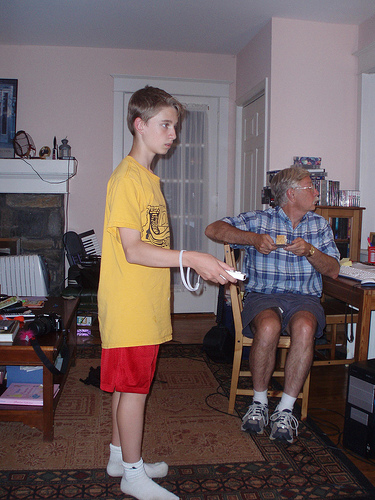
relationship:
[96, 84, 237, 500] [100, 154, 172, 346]
boy wearing shirt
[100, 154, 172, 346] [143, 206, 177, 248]
shirt has design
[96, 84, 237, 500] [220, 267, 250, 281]
boy holding wii remote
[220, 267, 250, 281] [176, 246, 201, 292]
wii remote has strap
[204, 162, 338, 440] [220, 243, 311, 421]
man sitting on top of chair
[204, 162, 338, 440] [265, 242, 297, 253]
man holding dish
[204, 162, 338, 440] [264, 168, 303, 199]
man has hair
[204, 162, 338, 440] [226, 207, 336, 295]
man wearing shirt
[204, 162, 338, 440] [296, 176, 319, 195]
man wearing glasses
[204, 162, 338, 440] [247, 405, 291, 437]
man wearing shoes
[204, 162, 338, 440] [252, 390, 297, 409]
man wearing socks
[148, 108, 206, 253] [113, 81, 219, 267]
curtain on door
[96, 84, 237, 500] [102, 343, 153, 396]
boy wearing shorts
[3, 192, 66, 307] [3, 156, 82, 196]
fireplace with mantel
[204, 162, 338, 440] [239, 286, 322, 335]
man wearing shorts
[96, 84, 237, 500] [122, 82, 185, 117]
boy has hair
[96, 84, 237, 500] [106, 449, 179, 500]
boy wearing socks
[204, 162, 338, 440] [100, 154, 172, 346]
man wearing shirt